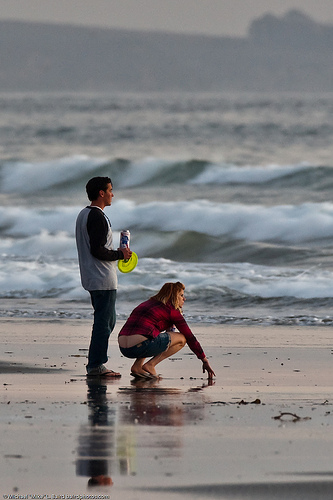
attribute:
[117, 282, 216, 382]
person —  two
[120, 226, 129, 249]
beverage — held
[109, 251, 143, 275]
disc — held, yellow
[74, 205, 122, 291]
shirt —  black and grey,  loose fitting, red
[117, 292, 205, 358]
shirt — plaid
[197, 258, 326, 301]
foam — white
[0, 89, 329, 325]
ocean — rough, blue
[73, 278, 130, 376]
jeans — blue denim, medium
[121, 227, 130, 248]
beer can — red white and blue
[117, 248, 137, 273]
frisbee — yellow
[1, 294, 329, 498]
sand — wet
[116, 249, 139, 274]
disk —  yellow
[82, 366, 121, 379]
sandals — black